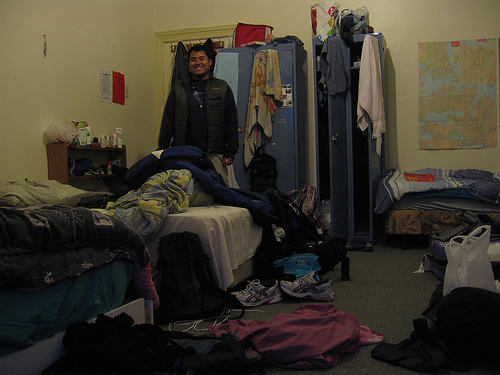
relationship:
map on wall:
[412, 36, 498, 148] [151, 1, 498, 249]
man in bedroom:
[167, 37, 236, 164] [0, 0, 499, 375]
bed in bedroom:
[383, 194, 500, 249] [0, 0, 499, 375]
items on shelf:
[50, 119, 123, 151] [51, 142, 133, 156]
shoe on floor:
[280, 270, 341, 302] [260, 247, 434, 339]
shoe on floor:
[230, 268, 336, 307] [260, 247, 434, 339]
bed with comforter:
[334, 153, 496, 243] [375, 165, 496, 214]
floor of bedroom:
[224, 244, 426, 373] [2, 3, 499, 370]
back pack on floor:
[151, 231, 245, 323] [353, 236, 415, 324]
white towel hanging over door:
[356, 33, 387, 155] [360, 34, 385, 252]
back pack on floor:
[149, 227, 257, 328] [0, 227, 499, 373]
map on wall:
[412, 36, 498, 148] [50, 1, 152, 58]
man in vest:
[158, 44, 240, 189] [172, 77, 254, 171]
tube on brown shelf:
[114, 122, 128, 156] [47, 135, 128, 189]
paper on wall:
[113, 74, 126, 103] [388, 23, 496, 164]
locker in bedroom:
[218, 32, 387, 245] [0, 0, 499, 375]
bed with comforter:
[383, 194, 500, 249] [373, 168, 499, 213]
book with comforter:
[401, 172, 436, 182] [373, 168, 499, 213]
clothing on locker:
[243, 48, 285, 165] [212, 36, 381, 241]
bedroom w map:
[0, 0, 499, 375] [412, 36, 498, 148]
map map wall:
[412, 36, 498, 148] [378, 6, 416, 169]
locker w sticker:
[256, 37, 306, 204] [276, 82, 293, 109]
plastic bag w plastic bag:
[455, 221, 492, 264] [442, 219, 497, 294]